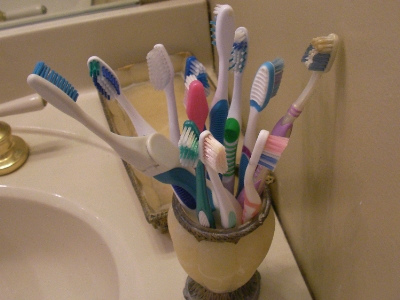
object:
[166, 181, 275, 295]
cup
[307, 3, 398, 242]
wall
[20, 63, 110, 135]
toothbrushes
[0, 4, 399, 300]
household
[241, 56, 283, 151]
toothbrush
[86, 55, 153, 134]
toothbrush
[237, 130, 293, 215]
toothbrush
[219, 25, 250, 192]
toothbrush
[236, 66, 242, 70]
bristles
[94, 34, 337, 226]
dish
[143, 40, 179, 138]
toothbrush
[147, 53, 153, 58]
bristles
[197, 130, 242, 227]
toothbrush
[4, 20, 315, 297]
sink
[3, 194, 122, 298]
indent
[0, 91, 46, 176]
faucet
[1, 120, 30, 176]
base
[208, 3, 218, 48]
edge